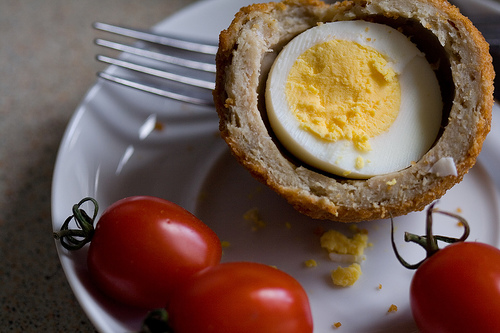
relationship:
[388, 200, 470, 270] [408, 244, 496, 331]
stem on top of tomato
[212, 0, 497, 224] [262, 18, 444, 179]
bread surrounding egg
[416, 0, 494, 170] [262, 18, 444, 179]
bread surrounding egg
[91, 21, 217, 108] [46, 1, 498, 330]
fork on plate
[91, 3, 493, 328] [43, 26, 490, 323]
breakfast on a plate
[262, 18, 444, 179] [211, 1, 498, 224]
egg surrounded bread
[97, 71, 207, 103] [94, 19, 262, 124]
tines of a fork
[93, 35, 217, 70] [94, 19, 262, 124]
tines of a fork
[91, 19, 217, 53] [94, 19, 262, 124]
tines of a fork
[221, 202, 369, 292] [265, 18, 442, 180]
crumbs of a egg yolk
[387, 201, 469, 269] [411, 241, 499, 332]
stem on a tomato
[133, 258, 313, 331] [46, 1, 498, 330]
tomato on plate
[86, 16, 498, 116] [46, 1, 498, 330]
fork laying on plate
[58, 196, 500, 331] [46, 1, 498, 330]
tomato on plate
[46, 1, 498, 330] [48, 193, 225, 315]
plate has food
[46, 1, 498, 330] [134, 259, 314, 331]
plate has food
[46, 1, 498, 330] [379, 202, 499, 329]
plate has food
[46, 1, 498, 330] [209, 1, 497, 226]
plate has food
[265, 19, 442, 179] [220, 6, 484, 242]
egg inside bread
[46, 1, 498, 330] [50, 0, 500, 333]
plate has breakfast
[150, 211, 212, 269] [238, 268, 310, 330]
light shining on tomato